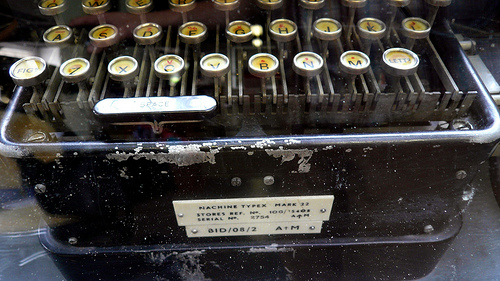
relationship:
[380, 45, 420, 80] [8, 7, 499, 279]
key on typewriter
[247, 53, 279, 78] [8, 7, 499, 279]
b key on typewriter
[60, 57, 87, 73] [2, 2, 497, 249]
key on typewriter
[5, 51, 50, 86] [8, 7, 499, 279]
key on typewriter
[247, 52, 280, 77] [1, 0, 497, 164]
b key on typewriter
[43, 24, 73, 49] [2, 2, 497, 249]
key on typewriter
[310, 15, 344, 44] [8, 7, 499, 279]
j key on typewriter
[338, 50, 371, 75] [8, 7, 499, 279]
key on typewriter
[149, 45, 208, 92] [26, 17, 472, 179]
key on typewriter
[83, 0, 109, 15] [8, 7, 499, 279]
w key on typewriter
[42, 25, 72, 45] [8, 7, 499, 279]
key on typewriter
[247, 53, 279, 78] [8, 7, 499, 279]
b key of typewriter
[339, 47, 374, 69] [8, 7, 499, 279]
key of typewriter